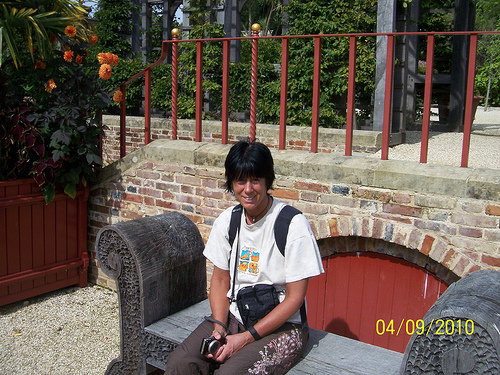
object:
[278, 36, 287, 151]
bar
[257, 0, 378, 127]
tree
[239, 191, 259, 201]
smiling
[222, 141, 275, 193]
hair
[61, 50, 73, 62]
flower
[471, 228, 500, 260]
wall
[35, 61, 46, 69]
flower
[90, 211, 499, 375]
bench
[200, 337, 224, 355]
camera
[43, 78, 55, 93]
flower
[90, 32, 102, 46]
flowers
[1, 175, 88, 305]
planter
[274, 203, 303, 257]
shoulder strap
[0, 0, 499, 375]
video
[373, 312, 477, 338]
time stamp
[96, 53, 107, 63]
flower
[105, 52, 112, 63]
flower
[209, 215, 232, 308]
arm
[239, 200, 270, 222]
necklace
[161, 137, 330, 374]
lady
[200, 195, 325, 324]
t shirt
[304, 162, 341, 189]
brick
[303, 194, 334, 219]
wall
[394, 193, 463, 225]
bricks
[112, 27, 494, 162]
rail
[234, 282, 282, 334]
fanny pack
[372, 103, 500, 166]
walkway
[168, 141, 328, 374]
man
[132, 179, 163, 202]
walls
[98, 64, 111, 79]
flower